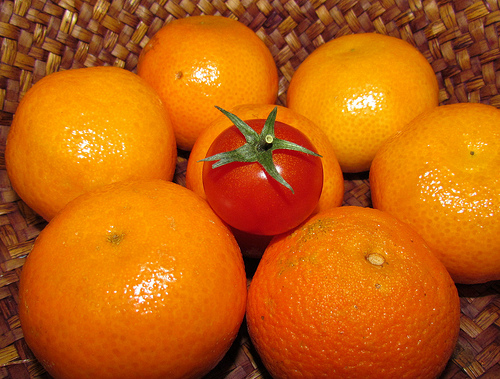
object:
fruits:
[17, 176, 246, 379]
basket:
[0, 0, 500, 379]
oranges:
[135, 11, 280, 151]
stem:
[256, 133, 276, 154]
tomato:
[198, 115, 326, 236]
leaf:
[212, 103, 258, 143]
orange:
[285, 31, 441, 174]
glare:
[340, 84, 385, 122]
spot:
[305, 124, 319, 134]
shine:
[53, 110, 132, 171]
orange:
[0, 64, 180, 226]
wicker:
[0, 0, 500, 379]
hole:
[359, 247, 395, 271]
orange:
[244, 205, 464, 376]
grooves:
[59, 103, 144, 136]